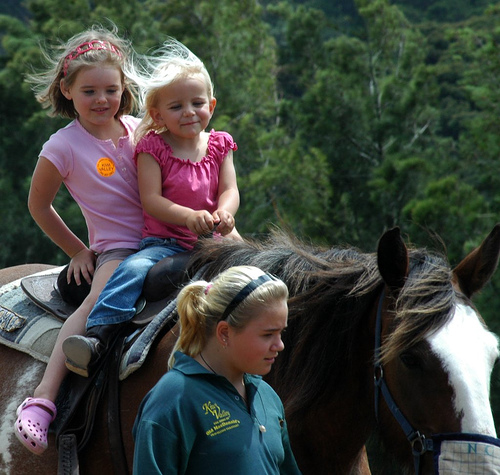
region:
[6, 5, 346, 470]
Three people in the foreground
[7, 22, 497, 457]
Two young girls on a horse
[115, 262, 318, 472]
A woman in a green shirt in the foreground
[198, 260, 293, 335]
Woman is wearing a black headband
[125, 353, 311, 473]
Woman is wearing a polo shirt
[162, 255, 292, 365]
Woman has blonde colored hair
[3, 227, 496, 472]
The horse's coat is dark brown and white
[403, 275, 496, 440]
Horse has a white stripe on its face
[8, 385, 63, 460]
Young girl is wearing pink shoes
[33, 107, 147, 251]
Young girl is wearing a pink shirt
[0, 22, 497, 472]
two young girls riding a horse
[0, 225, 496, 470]
young woman next to horse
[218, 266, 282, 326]
woman is wearing a black headband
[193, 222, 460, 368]
horse's mane is brown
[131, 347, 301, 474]
woman dressed in a blue-green polo shirt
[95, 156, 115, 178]
bright yellow sticker on older girl's shirt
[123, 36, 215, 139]
younger girl's blonde hair is blowing in the breeze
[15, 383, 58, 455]
girl wearing a shoe with ventilation holes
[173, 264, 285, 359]
woman's blonde hair is in a ponytail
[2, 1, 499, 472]
wall of green trees behind people and horse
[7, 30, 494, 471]
two girls riding a horse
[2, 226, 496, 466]
a brown horse with white hair on its nose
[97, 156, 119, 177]
an orange sticker on a pink shirt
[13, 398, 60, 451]
a girl wearing a pink sandal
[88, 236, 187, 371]
a girl wearing jeans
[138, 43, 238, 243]
a blonde girl wearing a pink shirt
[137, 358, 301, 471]
a green polo shirt with a yellow logo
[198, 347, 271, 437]
woman wearing a pendant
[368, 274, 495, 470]
a black harness on a horse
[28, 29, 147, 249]
a brown hair girl wearing a pink shirt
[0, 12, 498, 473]
three kids, one horse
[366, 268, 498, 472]
horse, rather inexplicably, wears feedbag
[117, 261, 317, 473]
teenage employee leads horse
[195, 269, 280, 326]
teenage employee wears red rubber band [maybe scrunchie], black ribbon headband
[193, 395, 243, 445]
employee wears work shirt w/ employer logo [something 'valley' i think]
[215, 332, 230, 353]
employee wears little earring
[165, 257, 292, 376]
employee has natural blonde hair, dark roots from less sun, in ponytail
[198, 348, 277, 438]
employee wears thin necklace w/ small white ornament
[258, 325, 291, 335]
employee's straight eyebrows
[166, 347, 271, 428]
henley-type collar on employee's teal shirt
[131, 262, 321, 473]
blond girl leading the horse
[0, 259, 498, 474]
brown and white horse with two children on it's back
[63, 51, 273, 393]
blond child on the back of the horse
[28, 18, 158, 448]
girl with brown haird riding the horse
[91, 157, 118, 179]
orange sticker on the girl's shirt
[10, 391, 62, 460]
pink crocs on the girl's foot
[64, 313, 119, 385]
black boot on the girl's foot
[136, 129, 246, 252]
dark pink on the blond girl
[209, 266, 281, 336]
black hair band in the girl's hair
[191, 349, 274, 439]
necklace on the girl's neck